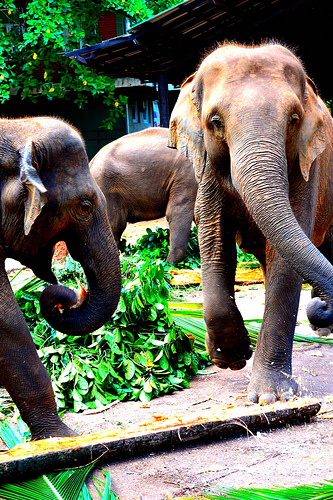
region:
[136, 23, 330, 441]
this is an elephant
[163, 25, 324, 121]
brown hair on elephant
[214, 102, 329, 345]
grey trunk of elepjant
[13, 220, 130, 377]
trunk of elephant is curls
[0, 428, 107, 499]
palm trees on ground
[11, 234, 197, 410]
pile of leafs on ground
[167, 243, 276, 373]
elephant has foot raised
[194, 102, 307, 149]
two eyes of elephant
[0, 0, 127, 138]
green tree in background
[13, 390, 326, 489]
split log on ground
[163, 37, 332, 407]
fuzzy brown and grey elephant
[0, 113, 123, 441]
fuzzy brown and grey elephant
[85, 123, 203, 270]
fuzzy brown and grey elephant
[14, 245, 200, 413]
leafy green plants on the ground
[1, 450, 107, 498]
green palm frond on the ground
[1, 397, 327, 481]
split log on the ground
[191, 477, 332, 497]
green palm frond on the ground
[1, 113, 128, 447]
elephant eating food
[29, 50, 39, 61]
little yellow leaf on a tree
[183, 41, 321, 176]
head of an elephant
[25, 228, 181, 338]
nose of an elephant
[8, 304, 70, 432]
leg of an elephant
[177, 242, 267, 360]
leg of an elephant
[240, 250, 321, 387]
leg of an elephant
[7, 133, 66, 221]
ear of an elephant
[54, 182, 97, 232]
eye of an elephant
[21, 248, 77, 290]
mouth of an elephant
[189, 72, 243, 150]
eye of an elephant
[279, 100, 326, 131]
eye of an elephant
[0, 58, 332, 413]
three elephants together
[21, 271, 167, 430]
green leaves on the ground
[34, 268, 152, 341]
curved trunk on elephant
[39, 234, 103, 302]
open mouth of elephant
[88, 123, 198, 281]
body of an elephant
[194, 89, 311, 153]
two eyes facing forward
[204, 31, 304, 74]
little hairs on top of head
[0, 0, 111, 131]
tree behind the elephants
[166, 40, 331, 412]
Elephant walking on the ground.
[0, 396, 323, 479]
split log on the ground.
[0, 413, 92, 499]
Green palm leaf on the ground.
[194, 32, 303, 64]
Brown hair on the elephant.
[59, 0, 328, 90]
roof on the structure.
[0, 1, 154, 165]
Building in the background.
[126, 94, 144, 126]
window in the house.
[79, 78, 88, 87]
Yellow flower on the tree.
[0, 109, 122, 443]
Elephant eating food.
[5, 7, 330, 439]
a group of elephants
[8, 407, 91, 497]
leaves on the ground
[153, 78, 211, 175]
ear on the elephant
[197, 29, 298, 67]
hair on the elephant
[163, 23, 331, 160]
brown head of elephant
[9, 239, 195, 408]
a pile of leaves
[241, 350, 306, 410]
foot of the elephant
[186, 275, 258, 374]
elephant foot it raised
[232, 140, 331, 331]
gray trunk of elephant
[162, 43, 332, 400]
a large gray elephant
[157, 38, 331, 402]
a hairy gray and pink elephant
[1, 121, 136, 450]
an elephant with a curled trunk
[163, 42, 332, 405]
an elephant with a swaying trunk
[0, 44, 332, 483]
three elephants in a display